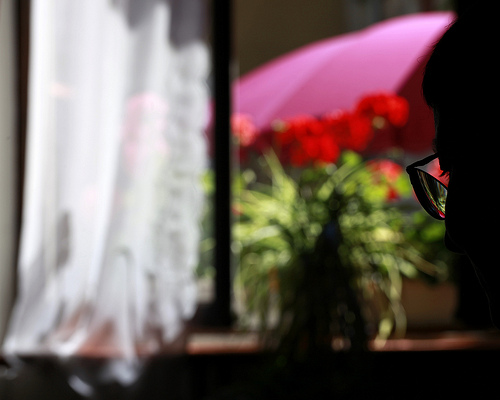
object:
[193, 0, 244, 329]
frame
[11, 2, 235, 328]
window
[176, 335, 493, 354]
sill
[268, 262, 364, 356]
vase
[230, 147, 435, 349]
stem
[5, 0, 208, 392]
curtain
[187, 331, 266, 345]
light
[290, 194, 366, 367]
object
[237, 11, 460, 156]
umbrella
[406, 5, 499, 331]
man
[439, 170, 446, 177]
eyelash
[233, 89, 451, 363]
flowers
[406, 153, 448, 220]
eyeglasses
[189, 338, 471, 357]
wood surface